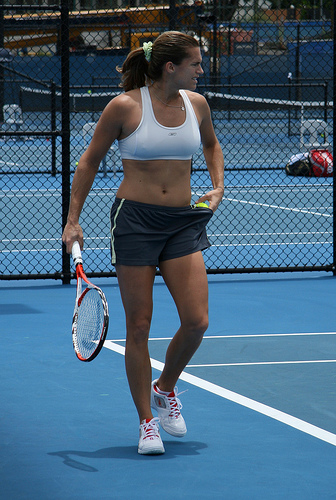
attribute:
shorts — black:
[106, 195, 213, 267]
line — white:
[111, 197, 122, 264]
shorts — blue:
[100, 189, 223, 272]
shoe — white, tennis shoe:
[149, 376, 189, 436]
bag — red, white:
[309, 148, 333, 175]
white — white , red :
[174, 421, 182, 431]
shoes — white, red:
[119, 378, 202, 437]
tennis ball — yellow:
[196, 202, 215, 210]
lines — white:
[90, 330, 333, 444]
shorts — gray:
[111, 188, 243, 288]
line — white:
[89, 337, 333, 449]